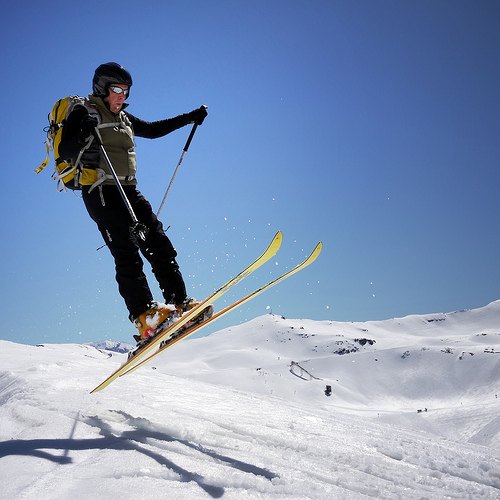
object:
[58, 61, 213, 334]
man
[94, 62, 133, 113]
head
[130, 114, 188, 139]
arm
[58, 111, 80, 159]
arm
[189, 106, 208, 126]
hand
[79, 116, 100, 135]
hand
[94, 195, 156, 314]
legs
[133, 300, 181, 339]
shoes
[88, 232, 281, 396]
skis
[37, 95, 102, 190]
backpack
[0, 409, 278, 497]
shadow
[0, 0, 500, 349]
sky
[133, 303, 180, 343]
boot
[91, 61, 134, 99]
helmet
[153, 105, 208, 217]
pole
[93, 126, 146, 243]
pole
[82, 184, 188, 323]
pants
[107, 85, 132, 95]
goggles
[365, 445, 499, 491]
trails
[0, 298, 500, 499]
snow